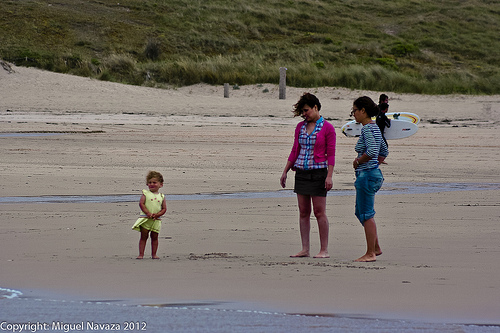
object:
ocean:
[1, 287, 500, 333]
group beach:
[131, 92, 389, 262]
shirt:
[354, 122, 389, 172]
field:
[0, 0, 500, 96]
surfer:
[378, 94, 389, 104]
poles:
[224, 67, 286, 99]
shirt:
[294, 115, 329, 169]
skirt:
[293, 169, 327, 198]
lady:
[280, 92, 337, 258]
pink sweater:
[288, 120, 337, 171]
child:
[132, 170, 168, 259]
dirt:
[0, 112, 500, 128]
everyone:
[131, 91, 389, 262]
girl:
[349, 96, 389, 262]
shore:
[0, 282, 499, 333]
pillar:
[279, 67, 287, 100]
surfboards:
[341, 112, 420, 140]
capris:
[354, 168, 384, 227]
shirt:
[138, 189, 165, 220]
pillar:
[224, 83, 230, 98]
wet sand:
[227, 200, 290, 212]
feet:
[290, 251, 330, 258]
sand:
[0, 131, 499, 199]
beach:
[0, 59, 498, 321]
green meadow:
[0, 0, 498, 94]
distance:
[0, 55, 500, 95]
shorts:
[293, 168, 328, 197]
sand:
[0, 189, 500, 318]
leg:
[352, 168, 384, 262]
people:
[375, 102, 391, 151]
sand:
[0, 60, 499, 133]